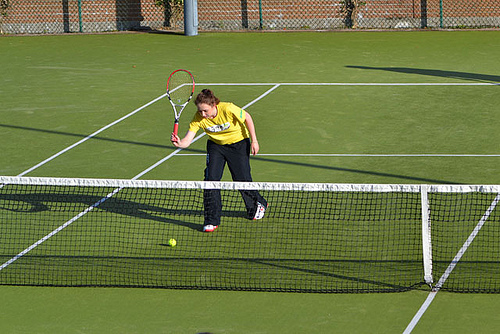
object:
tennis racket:
[164, 69, 196, 144]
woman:
[172, 88, 269, 232]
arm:
[173, 119, 202, 152]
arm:
[225, 104, 260, 156]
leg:
[228, 153, 269, 220]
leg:
[203, 155, 227, 233]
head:
[186, 88, 219, 120]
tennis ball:
[166, 238, 177, 248]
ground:
[0, 29, 499, 332]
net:
[0, 176, 499, 294]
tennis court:
[0, 1, 498, 333]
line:
[175, 151, 500, 159]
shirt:
[188, 102, 248, 145]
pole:
[183, 0, 199, 37]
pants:
[203, 140, 269, 226]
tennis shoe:
[203, 224, 220, 231]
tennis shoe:
[251, 203, 266, 221]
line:
[0, 84, 265, 273]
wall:
[1, 1, 499, 35]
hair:
[194, 88, 221, 108]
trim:
[1, 174, 499, 193]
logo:
[203, 123, 230, 133]